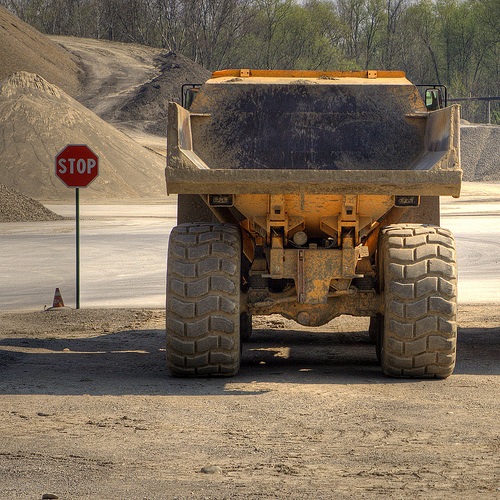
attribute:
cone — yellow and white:
[49, 285, 67, 311]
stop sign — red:
[53, 138, 99, 196]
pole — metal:
[73, 188, 79, 313]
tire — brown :
[164, 225, 249, 372]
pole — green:
[73, 186, 80, 310]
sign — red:
[53, 143, 100, 190]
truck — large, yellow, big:
[143, 56, 480, 391]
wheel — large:
[164, 220, 239, 377]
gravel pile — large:
[3, 71, 178, 204]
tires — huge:
[159, 199, 256, 399]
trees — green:
[4, 2, 499, 130]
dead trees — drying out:
[49, 0, 241, 67]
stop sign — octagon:
[54, 143, 97, 188]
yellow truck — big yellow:
[165, 65, 461, 377]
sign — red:
[30, 124, 122, 181]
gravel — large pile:
[4, 3, 233, 171]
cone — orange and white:
[51, 287, 65, 307]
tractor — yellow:
[149, 58, 486, 389]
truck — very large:
[162, 66, 464, 376]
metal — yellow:
[294, 288, 328, 319]